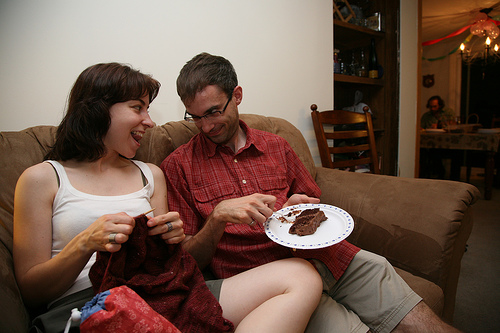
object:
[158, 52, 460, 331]
man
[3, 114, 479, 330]
sofa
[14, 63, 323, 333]
woman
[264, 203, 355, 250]
plate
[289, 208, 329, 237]
food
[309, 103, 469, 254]
chair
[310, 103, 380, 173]
back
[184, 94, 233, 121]
glasses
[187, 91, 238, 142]
face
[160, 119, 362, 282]
shirt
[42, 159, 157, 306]
tank top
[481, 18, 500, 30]
balloons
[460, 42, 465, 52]
light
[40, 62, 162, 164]
hair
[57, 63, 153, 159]
head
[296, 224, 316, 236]
desert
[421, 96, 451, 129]
man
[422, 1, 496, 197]
room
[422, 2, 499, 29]
ceiling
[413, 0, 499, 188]
doorway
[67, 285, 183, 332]
bag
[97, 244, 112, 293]
yarn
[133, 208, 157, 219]
needled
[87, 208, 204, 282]
knit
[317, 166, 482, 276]
arm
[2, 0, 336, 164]
wall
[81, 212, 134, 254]
hands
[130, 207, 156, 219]
needle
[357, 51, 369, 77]
bottles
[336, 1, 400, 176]
shelf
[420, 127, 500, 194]
table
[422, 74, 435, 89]
plaque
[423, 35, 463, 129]
wall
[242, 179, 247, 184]
buttons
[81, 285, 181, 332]
blanket